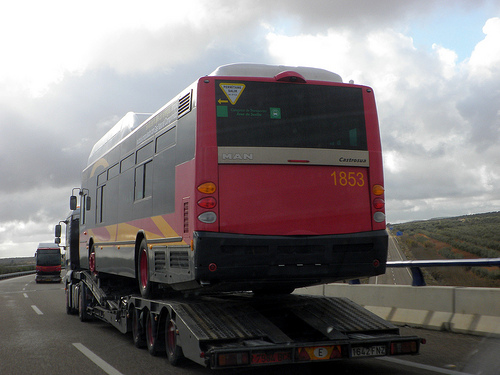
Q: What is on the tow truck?
A: Bus.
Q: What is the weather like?
A: Cloudy.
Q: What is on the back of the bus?
A: Windows.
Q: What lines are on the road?
A: White.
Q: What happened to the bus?
A: It needs to be towed.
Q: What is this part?
A: Flatbed.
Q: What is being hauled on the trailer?
A: Bus.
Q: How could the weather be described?
A: Cloudy.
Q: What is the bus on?
A: Trailer.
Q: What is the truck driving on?
A: Road.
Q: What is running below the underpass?
A: Another road.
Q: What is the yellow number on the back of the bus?
A: 1853.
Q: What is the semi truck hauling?
A: Bus.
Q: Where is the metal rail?
A: Overpass.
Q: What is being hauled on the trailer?
A: A bus.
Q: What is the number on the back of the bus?
A: 1853.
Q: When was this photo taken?
A: Daytime.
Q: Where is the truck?
A: On the highway.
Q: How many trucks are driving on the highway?
A: Two.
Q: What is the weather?
A: Cloudy.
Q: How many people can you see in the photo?
A: None.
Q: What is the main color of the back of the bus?
A: Red.